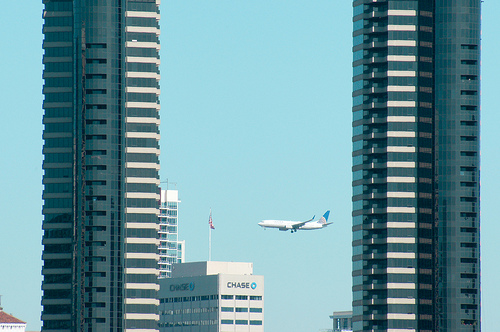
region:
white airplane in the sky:
[253, 202, 338, 237]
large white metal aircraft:
[253, 207, 338, 236]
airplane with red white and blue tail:
[253, 205, 335, 235]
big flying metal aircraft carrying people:
[250, 200, 340, 237]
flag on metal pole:
[203, 200, 220, 265]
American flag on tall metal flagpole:
[203, 200, 219, 264]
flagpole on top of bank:
[200, 205, 222, 262]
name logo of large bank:
[223, 277, 259, 291]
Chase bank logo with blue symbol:
[224, 277, 259, 289]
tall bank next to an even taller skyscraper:
[160, 255, 267, 329]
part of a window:
[373, 211, 383, 262]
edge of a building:
[373, 142, 374, 210]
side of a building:
[344, 194, 377, 267]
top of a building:
[217, 272, 227, 284]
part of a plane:
[275, 222, 282, 224]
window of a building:
[230, 295, 235, 307]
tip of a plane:
[328, 222, 329, 229]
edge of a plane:
[273, 220, 274, 225]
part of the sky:
[221, 92, 248, 159]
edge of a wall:
[216, 268, 219, 308]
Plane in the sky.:
[252, 204, 341, 244]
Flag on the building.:
[186, 196, 229, 250]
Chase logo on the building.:
[243, 276, 265, 297]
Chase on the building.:
[222, 277, 257, 297]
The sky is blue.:
[181, 20, 316, 97]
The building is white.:
[156, 265, 257, 330]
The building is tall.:
[352, 2, 485, 329]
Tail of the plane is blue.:
[315, 205, 342, 228]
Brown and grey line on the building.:
[73, 22, 96, 329]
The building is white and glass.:
[161, 185, 186, 283]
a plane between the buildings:
[250, 206, 337, 240]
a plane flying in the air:
[244, 207, 335, 247]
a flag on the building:
[205, 211, 218, 262]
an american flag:
[207, 209, 220, 231]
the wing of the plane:
[289, 214, 315, 231]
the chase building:
[165, 262, 267, 330]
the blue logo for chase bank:
[250, 279, 260, 289]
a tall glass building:
[36, 2, 163, 330]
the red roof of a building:
[0, 294, 31, 330]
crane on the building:
[157, 172, 182, 195]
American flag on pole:
[198, 211, 225, 261]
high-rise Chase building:
[157, 261, 267, 330]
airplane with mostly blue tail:
[258, 208, 337, 233]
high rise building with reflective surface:
[345, 1, 484, 330]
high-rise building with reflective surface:
[38, 1, 162, 330]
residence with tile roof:
[0, 303, 25, 330]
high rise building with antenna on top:
[161, 182, 188, 275]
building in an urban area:
[327, 312, 354, 330]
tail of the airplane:
[319, 209, 334, 229]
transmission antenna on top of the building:
[159, 176, 179, 192]